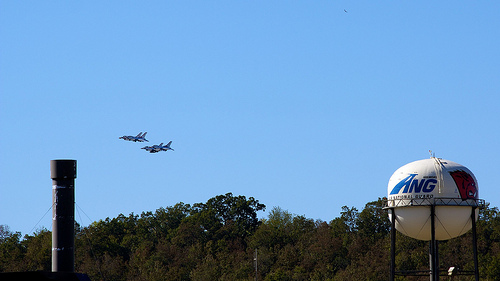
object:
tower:
[44, 157, 85, 278]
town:
[0, 152, 499, 280]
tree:
[190, 190, 268, 280]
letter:
[383, 172, 437, 195]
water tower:
[382, 150, 487, 280]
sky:
[2, 1, 500, 131]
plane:
[140, 136, 176, 157]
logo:
[448, 168, 484, 200]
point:
[426, 150, 443, 161]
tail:
[164, 138, 176, 148]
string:
[77, 202, 101, 229]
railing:
[382, 196, 487, 210]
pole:
[250, 240, 266, 280]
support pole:
[384, 209, 401, 280]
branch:
[340, 202, 360, 230]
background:
[0, 62, 498, 193]